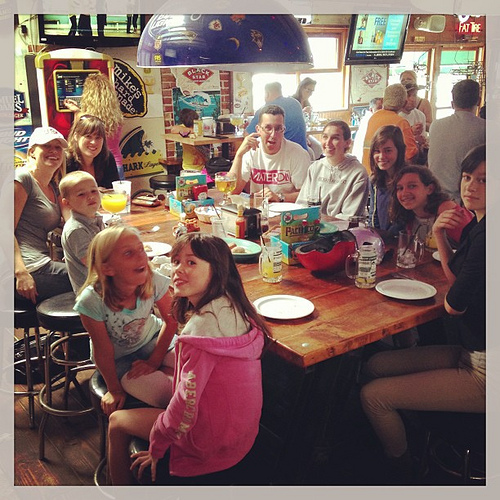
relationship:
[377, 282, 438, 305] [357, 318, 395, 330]
plate on table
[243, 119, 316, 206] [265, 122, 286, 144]
man in glasses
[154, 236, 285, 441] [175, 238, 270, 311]
girl with brown hair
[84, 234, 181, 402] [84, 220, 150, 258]
girl with blonde hair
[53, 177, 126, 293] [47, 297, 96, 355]
boy on barstool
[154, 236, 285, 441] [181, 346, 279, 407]
girl in jacket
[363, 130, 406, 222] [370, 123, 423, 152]
lady has dark hair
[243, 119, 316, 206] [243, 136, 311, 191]
man in shirt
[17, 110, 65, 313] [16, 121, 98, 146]
woman wearing baseball cap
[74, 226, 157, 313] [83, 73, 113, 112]
blonde hair with blonde hair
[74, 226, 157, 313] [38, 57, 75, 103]
blonde hair playing juke box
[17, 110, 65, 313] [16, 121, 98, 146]
woman in baseball cap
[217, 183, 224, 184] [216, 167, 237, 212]
beer in glass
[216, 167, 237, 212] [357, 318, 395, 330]
glass on table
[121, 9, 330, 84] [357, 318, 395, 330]
light over table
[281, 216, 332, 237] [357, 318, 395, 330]
menu on table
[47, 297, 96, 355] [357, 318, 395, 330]
barstool at table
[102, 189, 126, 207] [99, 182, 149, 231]
yellow drink in glass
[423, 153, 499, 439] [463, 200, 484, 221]
female touching chin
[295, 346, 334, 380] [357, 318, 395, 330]
part of table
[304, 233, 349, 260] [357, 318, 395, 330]
red helmet on table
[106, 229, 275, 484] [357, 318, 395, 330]
girl at table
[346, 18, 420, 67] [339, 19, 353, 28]
tv on wall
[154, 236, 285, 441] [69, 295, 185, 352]
girl in blue shirt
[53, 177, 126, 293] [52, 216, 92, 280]
boy in gray shirt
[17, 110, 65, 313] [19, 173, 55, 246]
woman in gray shirt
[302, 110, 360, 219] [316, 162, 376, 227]
woman in gray hoodie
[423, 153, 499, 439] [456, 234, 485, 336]
female in black shirt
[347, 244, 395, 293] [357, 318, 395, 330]
mug on table